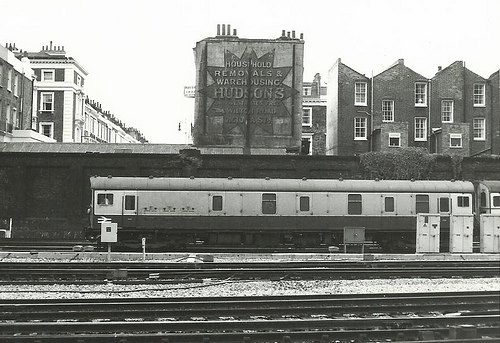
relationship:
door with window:
[102, 187, 187, 281] [84, 176, 184, 204]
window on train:
[207, 193, 224, 214] [84, 169, 493, 247]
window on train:
[263, 189, 282, 214] [84, 169, 493, 247]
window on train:
[299, 193, 316, 213] [84, 169, 493, 247]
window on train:
[347, 191, 360, 213] [84, 169, 493, 247]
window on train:
[386, 196, 392, 211] [84, 169, 493, 247]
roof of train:
[87, 173, 476, 195] [81, 165, 477, 243]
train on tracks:
[86, 175, 499, 249] [1, 240, 498, 342]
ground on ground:
[0, 240, 500, 343] [318, 279, 406, 293]